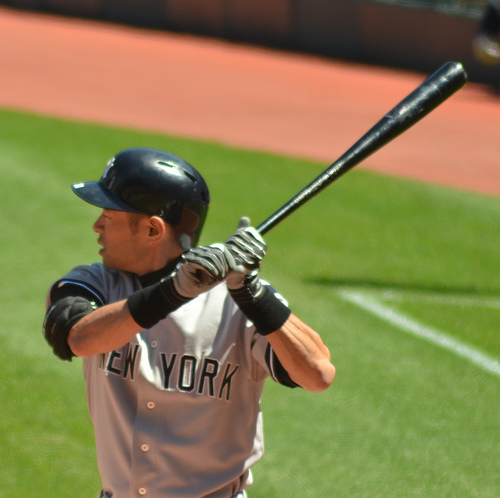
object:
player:
[44, 147, 335, 495]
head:
[88, 146, 211, 273]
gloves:
[173, 243, 230, 297]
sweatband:
[127, 276, 191, 329]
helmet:
[72, 147, 209, 245]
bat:
[201, 60, 467, 287]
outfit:
[43, 260, 297, 496]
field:
[0, 102, 495, 495]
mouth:
[97, 239, 108, 255]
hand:
[227, 215, 270, 311]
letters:
[159, 350, 175, 391]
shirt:
[47, 260, 299, 497]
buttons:
[147, 401, 155, 409]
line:
[334, 283, 497, 380]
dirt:
[2, 11, 498, 197]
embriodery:
[98, 341, 239, 402]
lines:
[392, 289, 496, 310]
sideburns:
[128, 215, 139, 234]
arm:
[47, 278, 178, 362]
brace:
[45, 284, 96, 362]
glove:
[228, 217, 259, 294]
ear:
[147, 217, 165, 246]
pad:
[14, 3, 497, 83]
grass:
[424, 464, 498, 487]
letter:
[218, 363, 238, 401]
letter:
[198, 358, 219, 397]